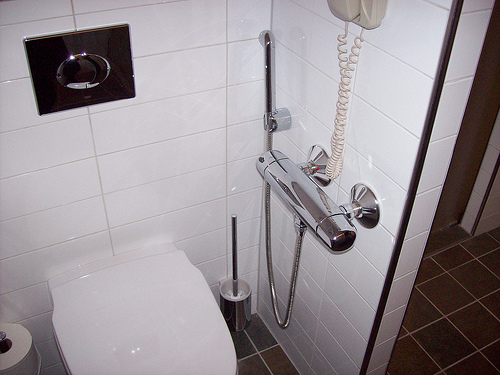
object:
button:
[56, 53, 111, 89]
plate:
[23, 23, 135, 116]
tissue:
[0, 318, 31, 372]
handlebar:
[254, 149, 357, 253]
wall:
[0, 0, 500, 375]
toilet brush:
[226, 218, 246, 299]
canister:
[219, 279, 252, 331]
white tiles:
[0, 0, 500, 375]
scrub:
[224, 215, 245, 300]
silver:
[23, 24, 136, 115]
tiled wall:
[0, 0, 497, 374]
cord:
[325, 23, 364, 180]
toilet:
[49, 243, 239, 374]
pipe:
[264, 32, 304, 329]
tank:
[46, 247, 239, 375]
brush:
[224, 214, 245, 299]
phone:
[327, 0, 384, 30]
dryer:
[255, 149, 357, 254]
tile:
[230, 223, 500, 375]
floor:
[231, 226, 499, 375]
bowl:
[50, 249, 235, 375]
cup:
[219, 277, 251, 330]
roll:
[0, 323, 39, 375]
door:
[361, 0, 500, 375]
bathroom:
[0, 0, 500, 375]